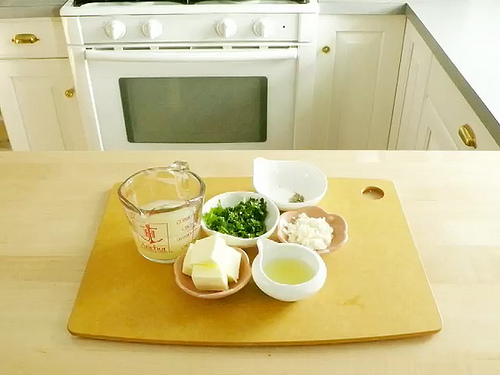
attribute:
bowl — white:
[276, 201, 349, 248]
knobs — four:
[101, 19, 274, 39]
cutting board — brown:
[69, 179, 436, 342]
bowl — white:
[248, 148, 329, 207]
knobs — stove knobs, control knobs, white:
[214, 15, 268, 43]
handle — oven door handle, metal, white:
[81, 45, 302, 65]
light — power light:
[280, 19, 292, 31]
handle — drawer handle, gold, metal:
[13, 36, 41, 45]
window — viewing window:
[120, 75, 278, 145]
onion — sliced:
[297, 214, 329, 243]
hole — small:
[365, 181, 383, 203]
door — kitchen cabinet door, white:
[316, 12, 391, 151]